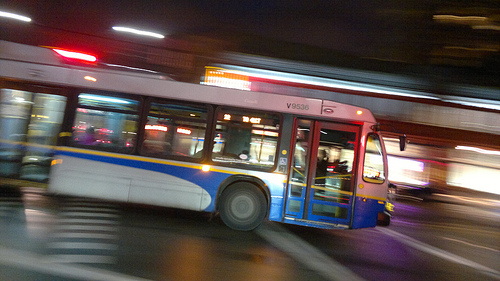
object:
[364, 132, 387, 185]
window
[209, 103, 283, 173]
window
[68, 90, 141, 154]
window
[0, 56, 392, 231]
glare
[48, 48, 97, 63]
light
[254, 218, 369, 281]
lines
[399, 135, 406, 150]
mirror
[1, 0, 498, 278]
intersection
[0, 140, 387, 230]
trim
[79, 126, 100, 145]
person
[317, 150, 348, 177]
driver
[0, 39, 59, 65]
air conditioning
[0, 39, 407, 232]
bus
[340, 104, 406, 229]
front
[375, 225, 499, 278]
line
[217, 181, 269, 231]
part of a wheel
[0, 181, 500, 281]
down street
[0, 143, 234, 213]
blue stripe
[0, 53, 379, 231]
side of bus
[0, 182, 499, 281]
painted on street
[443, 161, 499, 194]
an intersection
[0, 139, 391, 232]
white with blue trim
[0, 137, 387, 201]
yellow stripe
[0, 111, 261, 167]
people are sitting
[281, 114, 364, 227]
bus is closed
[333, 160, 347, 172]
steering wheel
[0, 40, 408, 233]
on the bus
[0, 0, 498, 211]
near an overpass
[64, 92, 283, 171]
windows on the bus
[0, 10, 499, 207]
street next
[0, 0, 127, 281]
blurry background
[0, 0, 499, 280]
photo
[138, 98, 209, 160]
this is the window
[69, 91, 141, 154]
side mirror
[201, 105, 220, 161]
black in color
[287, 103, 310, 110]
this is a writing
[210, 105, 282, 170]
glass